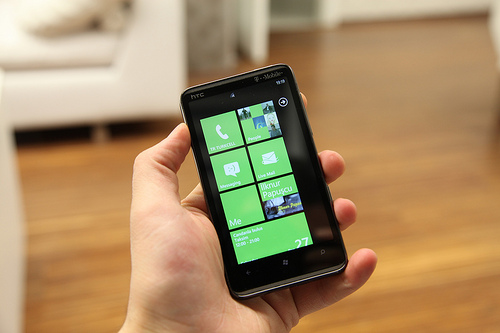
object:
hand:
[117, 121, 376, 333]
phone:
[179, 63, 348, 301]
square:
[200, 111, 245, 155]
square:
[210, 147, 255, 193]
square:
[248, 137, 293, 182]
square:
[237, 100, 282, 144]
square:
[219, 184, 265, 230]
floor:
[378, 32, 499, 333]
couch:
[0, 0, 188, 143]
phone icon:
[216, 125, 229, 140]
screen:
[179, 69, 339, 293]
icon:
[223, 162, 240, 177]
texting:
[220, 181, 240, 188]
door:
[268, 1, 321, 35]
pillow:
[0, 29, 118, 66]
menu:
[198, 101, 313, 265]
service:
[230, 93, 236, 99]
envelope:
[262, 151, 280, 165]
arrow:
[277, 97, 288, 107]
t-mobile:
[254, 71, 283, 82]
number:
[295, 237, 308, 248]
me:
[229, 218, 241, 226]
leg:
[91, 125, 111, 141]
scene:
[262, 193, 304, 220]